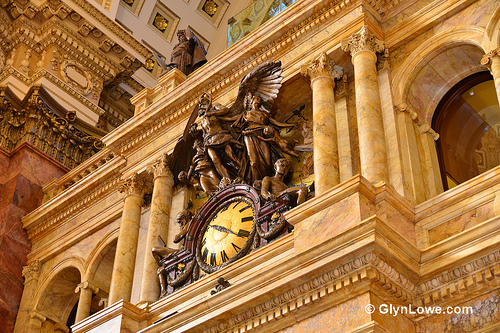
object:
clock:
[182, 183, 264, 278]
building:
[0, 0, 500, 333]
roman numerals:
[195, 201, 256, 266]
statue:
[149, 60, 309, 298]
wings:
[170, 60, 285, 190]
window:
[431, 69, 500, 193]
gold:
[1, 0, 500, 333]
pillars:
[104, 192, 146, 325]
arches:
[395, 27, 499, 206]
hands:
[204, 223, 244, 239]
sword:
[183, 91, 213, 142]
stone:
[1, 0, 500, 332]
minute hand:
[208, 223, 222, 232]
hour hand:
[219, 225, 244, 239]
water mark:
[364, 303, 475, 317]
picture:
[1, 0, 500, 332]